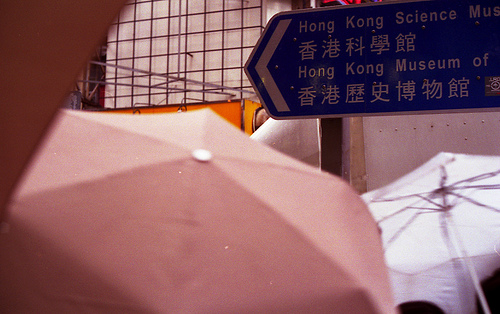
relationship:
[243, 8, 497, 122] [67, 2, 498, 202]
sign on a wall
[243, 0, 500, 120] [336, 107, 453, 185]
sign on wall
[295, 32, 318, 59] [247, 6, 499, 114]
character on sign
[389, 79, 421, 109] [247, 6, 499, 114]
character on sign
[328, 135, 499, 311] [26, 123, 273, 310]
umbrella next to umbrella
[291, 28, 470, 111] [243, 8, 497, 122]
letters on sign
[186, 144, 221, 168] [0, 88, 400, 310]
button on umbrella